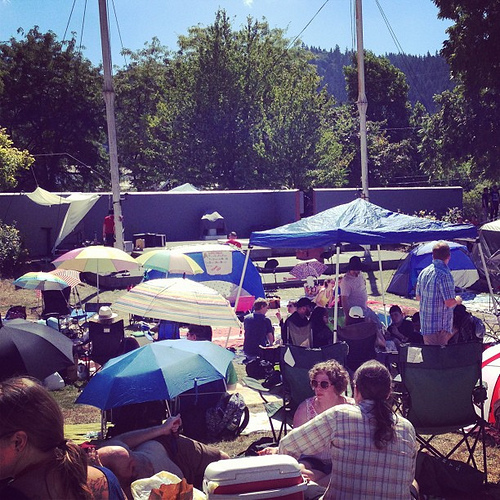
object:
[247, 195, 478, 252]
canopy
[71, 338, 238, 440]
umbrella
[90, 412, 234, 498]
person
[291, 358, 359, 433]
woman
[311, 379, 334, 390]
sunglasses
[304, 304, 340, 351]
people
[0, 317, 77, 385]
umbrella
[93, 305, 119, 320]
hat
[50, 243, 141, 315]
umbrella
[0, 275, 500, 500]
grass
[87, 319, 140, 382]
folding chair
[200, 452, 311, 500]
cooler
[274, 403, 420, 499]
shirt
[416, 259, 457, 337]
shirt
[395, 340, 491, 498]
chair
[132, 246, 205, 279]
umbrella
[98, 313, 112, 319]
stripe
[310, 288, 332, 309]
shirt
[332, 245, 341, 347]
poles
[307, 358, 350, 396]
hair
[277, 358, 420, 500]
man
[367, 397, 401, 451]
ponytail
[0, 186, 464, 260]
wall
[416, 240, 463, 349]
man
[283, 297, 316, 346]
person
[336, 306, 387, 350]
person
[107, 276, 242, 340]
umbrella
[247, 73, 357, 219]
tree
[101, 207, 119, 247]
people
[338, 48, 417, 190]
trees